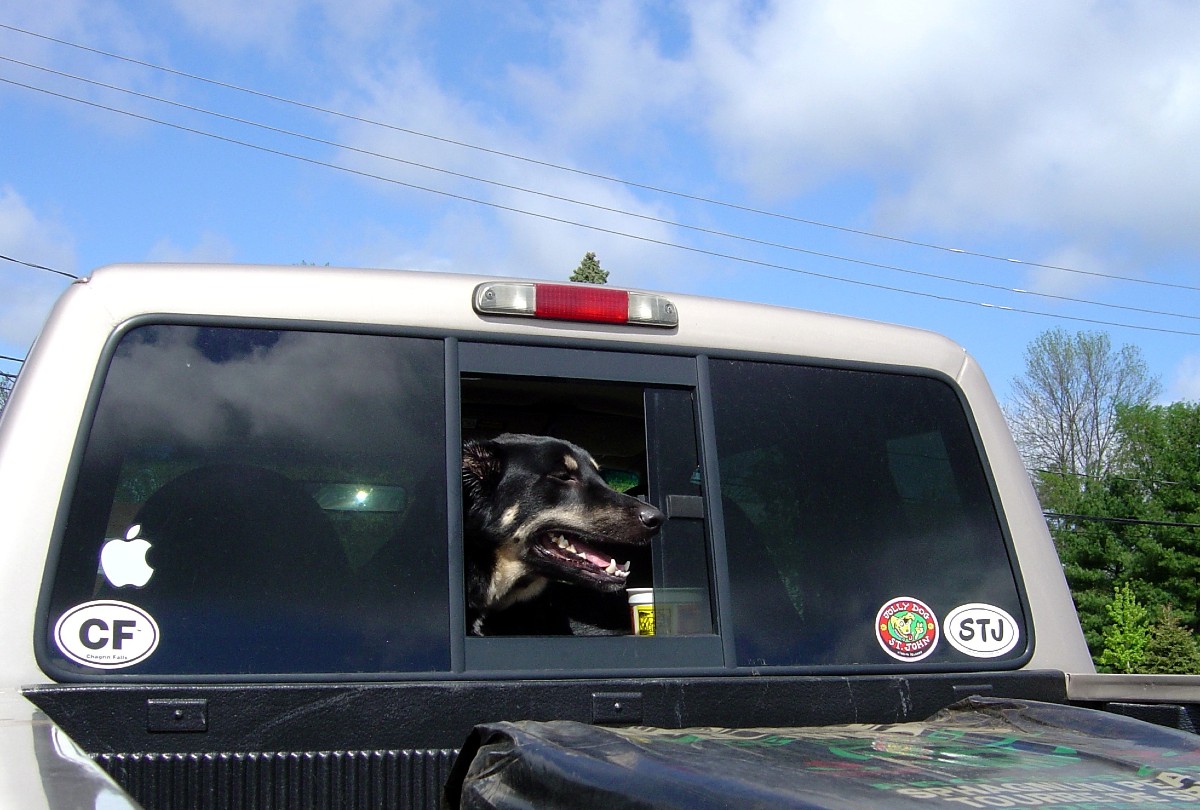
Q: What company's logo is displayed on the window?
A: Apple.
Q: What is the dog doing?
A: Sticking his head out the window.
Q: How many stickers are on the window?
A: 4.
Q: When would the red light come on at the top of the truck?
A: When the driver hits the brakes.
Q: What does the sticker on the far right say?
A: STJ.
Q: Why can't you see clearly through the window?
A: The window is tinted.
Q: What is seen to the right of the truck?
A: Trees.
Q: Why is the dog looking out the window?
A: To enjoy the breeze.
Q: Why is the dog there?
A: He is taking a ride.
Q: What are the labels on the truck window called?
A: Bumper stickers.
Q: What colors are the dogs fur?
A: Black and brown.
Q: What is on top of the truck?
A: A red light.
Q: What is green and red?
A: The sticker.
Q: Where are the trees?
A: On the side of the road.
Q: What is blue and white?
A: The sky.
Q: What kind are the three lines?
A: They are electric.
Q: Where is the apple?
A: On the truck's back window.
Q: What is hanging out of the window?
A: Dog.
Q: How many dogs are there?
A: 1.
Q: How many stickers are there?
A: 4.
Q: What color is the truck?
A: White.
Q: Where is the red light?
A: On top of the truck.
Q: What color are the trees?
A: Green.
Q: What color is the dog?
A: Black.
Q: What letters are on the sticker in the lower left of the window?
A: CF.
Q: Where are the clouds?
A: In the sky.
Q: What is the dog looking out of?
A: A window.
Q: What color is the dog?
A: Black.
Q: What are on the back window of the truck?
A: Stickers.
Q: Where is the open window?
A: The truck.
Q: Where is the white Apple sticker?
A: Window.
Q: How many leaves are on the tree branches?
A: None.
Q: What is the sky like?
A: Light blue with thin, white fleecy clouds.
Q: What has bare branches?
A: Tree.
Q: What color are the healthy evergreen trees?
A: Green.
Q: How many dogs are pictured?
A: One.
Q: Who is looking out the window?
A: A dog.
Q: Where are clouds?
A: In the sky.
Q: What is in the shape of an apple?
A: A sticker.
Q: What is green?
A: Trees.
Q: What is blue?
A: Sky.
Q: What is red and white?
A: Brake signal light.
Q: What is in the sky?
A: White clouds.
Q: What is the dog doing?
A: Peeking out the window.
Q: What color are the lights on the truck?
A: Red and white.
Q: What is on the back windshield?
A: Decals.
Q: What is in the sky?
A: White clouds.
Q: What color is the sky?
A: Blue.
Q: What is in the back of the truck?
A: Tarp.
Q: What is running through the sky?
A: Power lines.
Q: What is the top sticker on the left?
A: Apple.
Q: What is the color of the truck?
A: White.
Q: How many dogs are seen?
A: One.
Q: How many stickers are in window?
A: 4.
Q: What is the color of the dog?
A: Black and brown.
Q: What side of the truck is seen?
A: Rear side.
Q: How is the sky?
A: Clear with few clouds.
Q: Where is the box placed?
A: Back of the truck.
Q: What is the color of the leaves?
A: Green.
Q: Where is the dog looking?
A: Right side of the road.